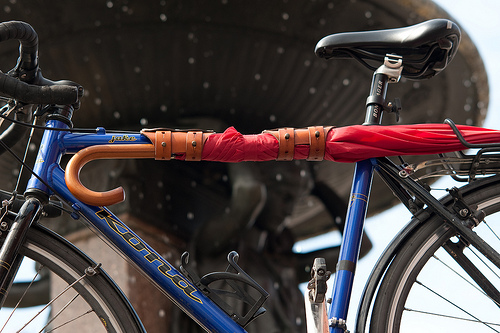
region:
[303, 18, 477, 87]
a black bike seat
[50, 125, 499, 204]
a red umbrella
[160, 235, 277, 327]
a black sports bottle holder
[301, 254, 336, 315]
a black bicycle pedal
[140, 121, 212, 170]
twp brown leather staps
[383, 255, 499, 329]
silver bicycle tire spokes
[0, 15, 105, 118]
black curved bicycle handle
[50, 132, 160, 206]
a brown wooden umbrella handle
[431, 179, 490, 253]
a black bicycle brake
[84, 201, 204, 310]
a black brand sticker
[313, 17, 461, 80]
a padded black seat on a bicycle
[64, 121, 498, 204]
a red umbrella attached to a bicycle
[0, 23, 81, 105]
a black handle bar on a bike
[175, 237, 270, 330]
a bottle holder on a bike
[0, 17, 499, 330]
a black and blue bike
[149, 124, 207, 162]
leather straps attaching an umbrella to a bicycle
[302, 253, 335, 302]
the foot pedal on a bicycle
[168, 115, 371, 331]
a female statue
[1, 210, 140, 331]
the front wheel on a bicycle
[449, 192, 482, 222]
the brake on a bicycle wheel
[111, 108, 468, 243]
Red umbrella on a bike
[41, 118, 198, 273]
Blue mountain bike frame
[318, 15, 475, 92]
Black seat on a mountain bike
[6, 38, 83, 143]
Black handle bars on a bike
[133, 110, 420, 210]
umbrella attached to bike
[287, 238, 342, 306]
black peddle on bike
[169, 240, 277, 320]
hold for a water bottle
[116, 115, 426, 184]
red umbrella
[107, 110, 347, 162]
Leather straps on bike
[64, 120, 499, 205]
red and brown umbrella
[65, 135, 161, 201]
brown wooden holder of umbrella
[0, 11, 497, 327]
black and blue bicycle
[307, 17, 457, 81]
little black seat of bicycle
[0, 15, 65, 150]
black handlebar of bicycle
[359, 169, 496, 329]
black back wheel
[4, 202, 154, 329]
black front wheel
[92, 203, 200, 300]
black letters on blue bicycle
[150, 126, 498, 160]
red umbrella on bicycle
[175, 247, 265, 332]
black mesh for water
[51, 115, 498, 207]
Red umbrella strapped to the bike frame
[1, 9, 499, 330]
Black and blue bicycle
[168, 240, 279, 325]
Water bottle holder attached to the frame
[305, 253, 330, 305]
Bicycle pedal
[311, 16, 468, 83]
Black leather bicycle seat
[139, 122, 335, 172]
Orange belt wrapped around the umbrella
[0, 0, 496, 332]
Statue of a woman in the background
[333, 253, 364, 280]
Black tape wrapped around the frame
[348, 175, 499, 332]
Thin bicycle tires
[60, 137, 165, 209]
Wooden umbrella handle